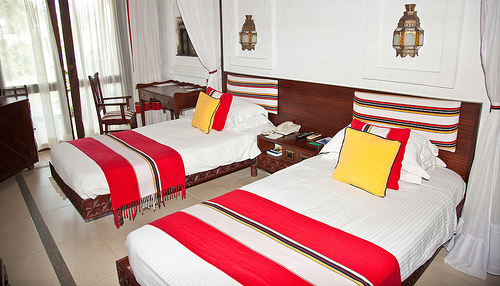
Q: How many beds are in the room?
A: Two.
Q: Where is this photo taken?
A: A bedroom.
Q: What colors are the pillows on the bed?
A: Red, white and yellow.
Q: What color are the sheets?
A: White.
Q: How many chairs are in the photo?
A: One.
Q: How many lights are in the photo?
A: Two.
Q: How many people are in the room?
A: None.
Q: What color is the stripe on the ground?
A: Grey.